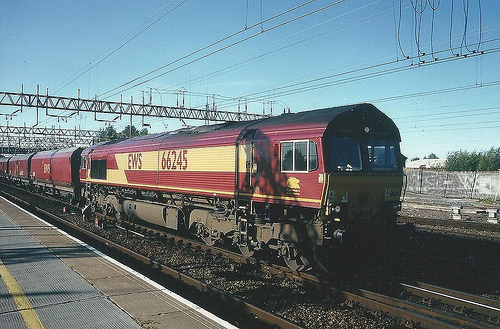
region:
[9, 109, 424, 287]
a train on train tracks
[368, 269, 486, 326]
train tracks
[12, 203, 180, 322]
the platform next to train tracks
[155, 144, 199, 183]
numbers on the side of a train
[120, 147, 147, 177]
letters on the side of a train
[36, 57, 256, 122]
wires above a train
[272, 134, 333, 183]
a window on a train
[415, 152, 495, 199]
cement walls along side a train track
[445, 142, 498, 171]
green trees near a train track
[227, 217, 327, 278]
the wheels of a train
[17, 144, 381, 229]
red and yellow train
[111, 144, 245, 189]
red numbers on train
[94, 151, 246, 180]
yellow stripe on train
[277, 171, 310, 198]
yellow logo on train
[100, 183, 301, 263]
brown wheels on train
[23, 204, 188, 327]
white line on platform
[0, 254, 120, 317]
grey bricks on sidewalk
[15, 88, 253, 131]
bower lines over train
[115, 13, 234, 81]
sky is blue and clear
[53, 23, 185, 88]
no clouds in sky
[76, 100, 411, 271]
a burgundy and yellow railroad car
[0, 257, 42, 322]
a wide yellow line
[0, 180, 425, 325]
railroad tracks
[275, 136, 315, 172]
a side window in the traincar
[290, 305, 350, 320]
a small section of gravel between the train tracks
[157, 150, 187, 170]
burgundy numbers on the side of a train car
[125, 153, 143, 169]
three burgundy letters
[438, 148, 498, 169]
the treetops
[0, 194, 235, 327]
a white line on a concrete platform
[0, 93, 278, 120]
a metal girder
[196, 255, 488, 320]
railway track at the railway station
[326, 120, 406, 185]
glasses infront of the train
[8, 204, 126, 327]
railway platform with railway track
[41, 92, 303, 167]
eletric train with electric post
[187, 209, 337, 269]
wheel of the train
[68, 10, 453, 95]
sky with electric lines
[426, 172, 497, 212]
compound of the railway station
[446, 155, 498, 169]
trees near the railway compound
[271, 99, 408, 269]
engine of the train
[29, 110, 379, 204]
brown and yellow colour train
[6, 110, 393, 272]
red train traveling down tracks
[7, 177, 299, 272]
black wheels of train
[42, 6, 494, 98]
wires running above train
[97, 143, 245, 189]
tan stripe on first train car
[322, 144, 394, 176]
front windows of train car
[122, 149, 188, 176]
red lettering on side of train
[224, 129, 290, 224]
shadow on side of train car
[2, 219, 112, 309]
shadow on train platform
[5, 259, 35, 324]
yellow stripe on platform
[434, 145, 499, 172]
two trees in the background